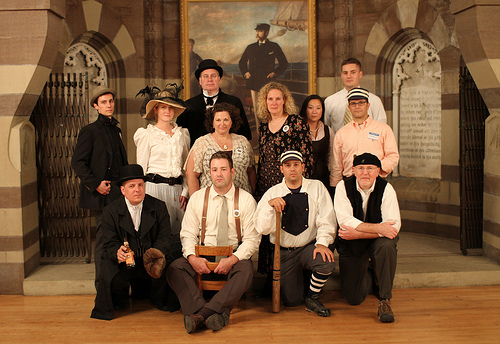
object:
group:
[71, 58, 402, 334]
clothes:
[72, 85, 399, 322]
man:
[166, 151, 262, 334]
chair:
[195, 244, 233, 296]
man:
[253, 151, 337, 317]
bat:
[271, 205, 281, 313]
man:
[89, 163, 181, 320]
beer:
[124, 237, 136, 269]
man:
[175, 59, 252, 149]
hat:
[194, 59, 223, 82]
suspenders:
[201, 186, 242, 246]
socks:
[309, 271, 332, 293]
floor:
[1, 285, 498, 344]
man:
[330, 88, 400, 187]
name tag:
[368, 132, 379, 140]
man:
[334, 152, 402, 323]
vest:
[343, 174, 388, 224]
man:
[324, 58, 388, 134]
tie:
[343, 103, 352, 125]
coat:
[89, 194, 175, 321]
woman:
[255, 82, 314, 204]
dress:
[254, 114, 316, 203]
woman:
[133, 90, 191, 237]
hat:
[135, 82, 189, 120]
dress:
[133, 121, 190, 235]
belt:
[146, 173, 183, 186]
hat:
[346, 88, 369, 106]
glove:
[143, 247, 166, 278]